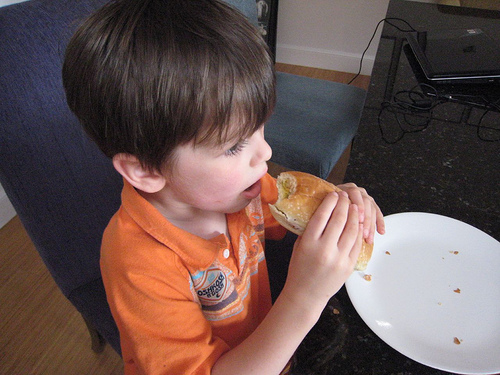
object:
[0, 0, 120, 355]
chair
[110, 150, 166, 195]
ear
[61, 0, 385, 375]
boy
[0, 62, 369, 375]
floor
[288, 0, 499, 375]
granite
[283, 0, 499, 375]
countertop